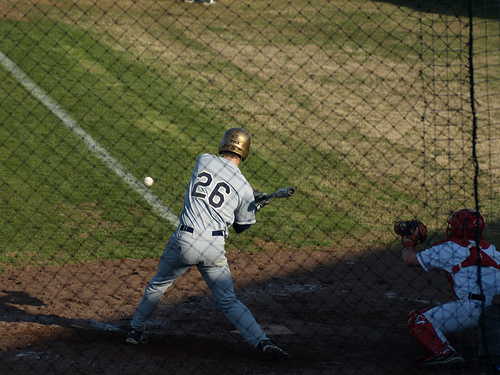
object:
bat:
[266, 187, 295, 200]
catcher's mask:
[445, 208, 485, 240]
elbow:
[233, 222, 252, 234]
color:
[23, 66, 137, 136]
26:
[190, 170, 232, 209]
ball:
[143, 176, 155, 187]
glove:
[393, 219, 428, 246]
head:
[222, 127, 251, 159]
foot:
[125, 326, 150, 345]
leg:
[197, 261, 270, 348]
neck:
[223, 152, 240, 167]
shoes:
[126, 330, 149, 346]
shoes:
[256, 339, 292, 364]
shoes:
[413, 352, 465, 368]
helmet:
[219, 127, 251, 162]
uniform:
[131, 153, 272, 349]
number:
[191, 171, 231, 209]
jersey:
[181, 152, 255, 233]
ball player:
[125, 127, 292, 364]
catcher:
[392, 208, 499, 368]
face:
[446, 219, 454, 240]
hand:
[403, 227, 419, 247]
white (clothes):
[463, 271, 488, 287]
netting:
[0, 0, 500, 375]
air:
[10, 7, 485, 237]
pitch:
[143, 176, 154, 187]